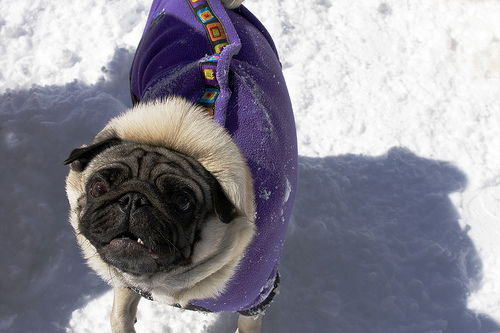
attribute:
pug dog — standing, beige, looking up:
[62, 0, 298, 333]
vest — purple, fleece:
[129, 0, 300, 317]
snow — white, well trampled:
[0, 0, 500, 331]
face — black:
[79, 162, 205, 276]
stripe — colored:
[187, 0, 230, 122]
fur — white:
[64, 95, 256, 310]